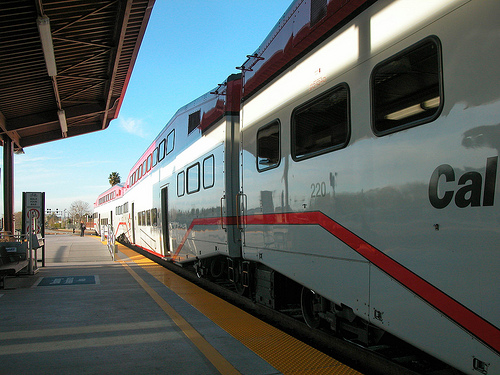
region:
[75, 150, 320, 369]
train is at the platform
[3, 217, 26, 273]
bench at the station wait area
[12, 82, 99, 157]
overhang cover for waiting passengers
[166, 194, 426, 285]
train has a red stripe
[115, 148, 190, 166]
windows on top deck of train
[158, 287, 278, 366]
textured yellow marking on platform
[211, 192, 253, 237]
handles on side of train car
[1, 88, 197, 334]
waiting area on platform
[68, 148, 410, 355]
train parked on the tracks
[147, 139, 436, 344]
train is white and red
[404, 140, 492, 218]
"Cal" is on the train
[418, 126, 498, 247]
The rest of the logo is cut off here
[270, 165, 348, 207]
"220" is on the train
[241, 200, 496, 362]
Red stripes has been painted on the train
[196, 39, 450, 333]
The train is red and white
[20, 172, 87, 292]
This is a sign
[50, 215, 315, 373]
Yellow stripes on the road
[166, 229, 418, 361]
These are the train's wheels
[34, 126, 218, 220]
Clouds are in the sky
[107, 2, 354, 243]
It is sunny outside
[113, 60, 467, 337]
train pulling into the station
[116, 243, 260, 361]
yellow stripe on platform edge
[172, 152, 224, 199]
passenger windows on train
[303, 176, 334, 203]
numbers on the side of a train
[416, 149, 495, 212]
words on the side of a train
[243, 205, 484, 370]
red stripe on the side of a train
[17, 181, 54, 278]
information sign on train platform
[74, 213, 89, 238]
person waiting to board the train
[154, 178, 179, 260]
open door on a train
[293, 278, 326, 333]
wheel on a train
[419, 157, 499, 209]
black text on the side of a train reading Cal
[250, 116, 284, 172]
train window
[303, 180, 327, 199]
black text reading 220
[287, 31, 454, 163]
two train windows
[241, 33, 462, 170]
three train windows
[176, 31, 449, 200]
six train windows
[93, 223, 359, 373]
yellow strip on the train platform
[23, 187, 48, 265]
long sign at a train station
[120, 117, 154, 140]
white cloud in the sky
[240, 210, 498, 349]
red design on the train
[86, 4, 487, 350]
the train is white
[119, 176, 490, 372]
red line on train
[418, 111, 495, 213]
black letters on train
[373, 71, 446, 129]
lights turned on in train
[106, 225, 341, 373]
the platform is yellow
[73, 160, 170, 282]
sun shining on end of train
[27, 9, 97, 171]
ceiling lights turned off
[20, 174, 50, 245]
the sign is white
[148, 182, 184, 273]
train door is open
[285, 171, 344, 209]
number 220 on train